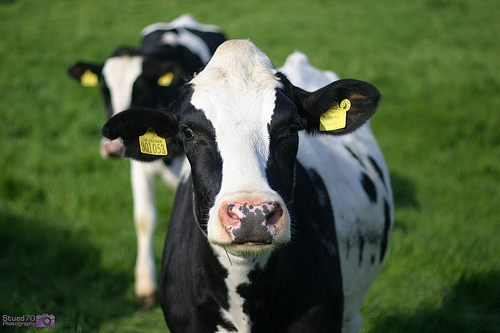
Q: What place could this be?
A: It is a field.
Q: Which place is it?
A: It is a field.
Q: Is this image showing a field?
A: Yes, it is showing a field.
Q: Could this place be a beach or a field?
A: It is a field.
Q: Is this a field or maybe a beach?
A: It is a field.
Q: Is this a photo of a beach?
A: No, the picture is showing a field.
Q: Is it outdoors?
A: Yes, it is outdoors.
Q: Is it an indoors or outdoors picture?
A: It is outdoors.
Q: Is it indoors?
A: No, it is outdoors.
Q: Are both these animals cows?
A: Yes, all the animals are cows.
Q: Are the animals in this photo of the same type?
A: Yes, all the animals are cows.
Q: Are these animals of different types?
A: No, all the animals are cows.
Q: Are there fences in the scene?
A: No, there are no fences.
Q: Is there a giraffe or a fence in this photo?
A: No, there are no fences or giraffes.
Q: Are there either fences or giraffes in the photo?
A: No, there are no fences or giraffes.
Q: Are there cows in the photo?
A: Yes, there is a cow.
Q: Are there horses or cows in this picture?
A: Yes, there is a cow.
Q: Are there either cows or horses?
A: Yes, there is a cow.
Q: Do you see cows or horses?
A: Yes, there is a cow.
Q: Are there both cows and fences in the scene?
A: No, there is a cow but no fences.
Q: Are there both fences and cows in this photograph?
A: No, there is a cow but no fences.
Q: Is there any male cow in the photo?
A: Yes, there is a male cow.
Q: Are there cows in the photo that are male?
A: Yes, there is a cow that is male.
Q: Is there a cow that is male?
A: Yes, there is a cow that is male.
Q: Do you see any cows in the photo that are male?
A: Yes, there is a cow that is male.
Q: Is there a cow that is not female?
A: Yes, there is a male cow.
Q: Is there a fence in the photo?
A: No, there are no fences.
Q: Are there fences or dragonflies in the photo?
A: No, there are no fences or dragonflies.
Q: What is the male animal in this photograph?
A: The animal is a cow.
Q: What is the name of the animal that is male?
A: The animal is a cow.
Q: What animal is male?
A: The animal is a cow.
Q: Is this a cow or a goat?
A: This is a cow.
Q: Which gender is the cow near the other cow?
A: The cow is male.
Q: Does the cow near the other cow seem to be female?
A: No, the cow is male.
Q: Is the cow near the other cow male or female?
A: The cow is male.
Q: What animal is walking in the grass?
A: The cow is walking in the grass.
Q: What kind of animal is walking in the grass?
A: The animal is a cow.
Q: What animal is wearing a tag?
A: The cow is wearing a tag.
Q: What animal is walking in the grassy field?
A: The cow is walking in the field.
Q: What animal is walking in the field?
A: The cow is walking in the field.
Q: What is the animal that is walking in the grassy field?
A: The animal is a cow.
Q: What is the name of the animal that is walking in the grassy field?
A: The animal is a cow.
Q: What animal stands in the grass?
A: The cow stands in the grass.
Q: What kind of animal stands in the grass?
A: The animal is a cow.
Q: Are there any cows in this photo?
A: Yes, there is a cow.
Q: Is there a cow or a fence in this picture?
A: Yes, there is a cow.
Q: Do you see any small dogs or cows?
A: Yes, there is a small cow.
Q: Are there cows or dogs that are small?
A: Yes, the cow is small.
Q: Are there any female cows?
A: Yes, there is a female cow.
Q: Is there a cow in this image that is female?
A: Yes, there is a cow that is female.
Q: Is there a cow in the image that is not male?
A: Yes, there is a female cow.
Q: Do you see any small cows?
A: Yes, there is a small cow.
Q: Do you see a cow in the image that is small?
A: Yes, there is a cow that is small.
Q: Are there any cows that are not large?
A: Yes, there is a small cow.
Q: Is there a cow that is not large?
A: Yes, there is a small cow.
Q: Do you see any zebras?
A: No, there are no zebras.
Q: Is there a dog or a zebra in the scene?
A: No, there are no zebras or dogs.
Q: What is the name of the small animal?
A: The animal is a cow.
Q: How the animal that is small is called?
A: The animal is a cow.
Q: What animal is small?
A: The animal is a cow.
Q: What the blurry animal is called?
A: The animal is a cow.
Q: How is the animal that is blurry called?
A: The animal is a cow.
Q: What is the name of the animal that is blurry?
A: The animal is a cow.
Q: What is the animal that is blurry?
A: The animal is a cow.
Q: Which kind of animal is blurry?
A: The animal is a cow.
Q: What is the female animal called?
A: The animal is a cow.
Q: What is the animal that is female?
A: The animal is a cow.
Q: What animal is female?
A: The animal is a cow.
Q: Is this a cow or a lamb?
A: This is a cow.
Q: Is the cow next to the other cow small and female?
A: Yes, the cow is small and female.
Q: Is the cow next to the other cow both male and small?
A: No, the cow is small but female.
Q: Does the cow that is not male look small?
A: Yes, the cow is small.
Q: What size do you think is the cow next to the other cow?
A: The cow is small.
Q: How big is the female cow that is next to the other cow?
A: The cow is small.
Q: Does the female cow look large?
A: No, the cow is small.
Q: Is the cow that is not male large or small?
A: The cow is small.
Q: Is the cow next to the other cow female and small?
A: Yes, the cow is female and small.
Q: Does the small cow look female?
A: Yes, the cow is female.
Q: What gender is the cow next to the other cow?
A: The cow is female.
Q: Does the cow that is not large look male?
A: No, the cow is female.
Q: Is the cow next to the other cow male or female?
A: The cow is female.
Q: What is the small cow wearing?
A: The cow is wearing a tag.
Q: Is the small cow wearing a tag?
A: Yes, the cow is wearing a tag.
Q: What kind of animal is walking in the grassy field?
A: The animal is a cow.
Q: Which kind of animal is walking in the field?
A: The animal is a cow.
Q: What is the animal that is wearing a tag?
A: The animal is a cow.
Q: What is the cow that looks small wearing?
A: The cow is wearing a tag.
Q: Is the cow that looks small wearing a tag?
A: Yes, the cow is wearing a tag.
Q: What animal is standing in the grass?
A: The cow is standing in the grass.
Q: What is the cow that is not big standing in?
A: The cow is standing in the grass.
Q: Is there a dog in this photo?
A: No, there are no dogs.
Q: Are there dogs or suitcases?
A: No, there are no dogs or suitcases.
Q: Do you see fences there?
A: No, there are no fences.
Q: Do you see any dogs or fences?
A: No, there are no fences or dogs.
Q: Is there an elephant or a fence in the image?
A: No, there are no fences or elephants.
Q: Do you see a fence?
A: No, there are no fences.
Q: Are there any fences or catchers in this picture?
A: No, there are no fences or catchers.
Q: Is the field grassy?
A: Yes, the field is grassy.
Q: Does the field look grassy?
A: Yes, the field is grassy.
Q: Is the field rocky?
A: No, the field is grassy.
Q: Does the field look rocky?
A: No, the field is grassy.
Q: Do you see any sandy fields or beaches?
A: No, there is a field but it is grassy.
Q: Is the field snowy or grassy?
A: The field is grassy.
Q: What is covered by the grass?
A: The field is covered by the grass.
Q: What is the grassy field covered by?
A: The field is covered by the grass.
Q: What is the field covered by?
A: The field is covered by the grass.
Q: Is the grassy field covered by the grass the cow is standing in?
A: Yes, the field is covered by the grass.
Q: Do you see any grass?
A: Yes, there is grass.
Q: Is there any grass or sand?
A: Yes, there is grass.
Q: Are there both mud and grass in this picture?
A: No, there is grass but no mud.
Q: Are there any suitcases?
A: No, there are no suitcases.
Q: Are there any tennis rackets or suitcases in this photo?
A: No, there are no suitcases or tennis rackets.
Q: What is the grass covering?
A: The grass is covering the field.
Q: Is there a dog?
A: No, there are no dogs.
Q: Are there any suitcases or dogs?
A: No, there are no dogs or suitcases.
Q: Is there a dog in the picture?
A: No, there are no dogs.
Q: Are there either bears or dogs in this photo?
A: No, there are no dogs or bears.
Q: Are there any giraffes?
A: No, there are no giraffes.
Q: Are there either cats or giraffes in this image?
A: No, there are no giraffes or cats.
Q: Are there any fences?
A: No, there are no fences.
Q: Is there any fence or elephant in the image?
A: No, there are no fences or elephants.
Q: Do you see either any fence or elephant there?
A: No, there are no fences or elephants.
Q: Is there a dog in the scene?
A: No, there are no dogs.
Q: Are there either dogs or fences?
A: No, there are no dogs or fences.